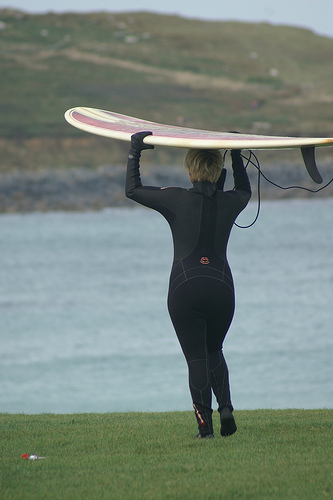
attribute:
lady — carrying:
[111, 141, 293, 469]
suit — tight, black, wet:
[136, 177, 274, 313]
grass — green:
[122, 422, 151, 432]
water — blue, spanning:
[92, 261, 155, 291]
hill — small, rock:
[225, 27, 308, 68]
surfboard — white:
[188, 99, 305, 189]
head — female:
[199, 155, 220, 181]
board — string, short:
[118, 64, 298, 224]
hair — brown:
[191, 141, 231, 177]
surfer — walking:
[140, 85, 308, 173]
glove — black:
[132, 119, 169, 156]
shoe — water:
[185, 395, 255, 453]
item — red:
[176, 234, 221, 274]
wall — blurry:
[20, 144, 97, 210]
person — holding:
[97, 74, 273, 387]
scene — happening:
[20, 75, 311, 440]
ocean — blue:
[57, 249, 134, 315]